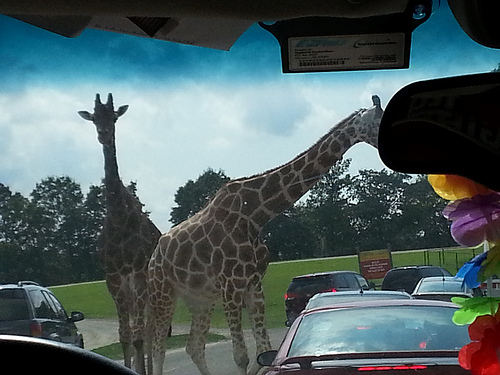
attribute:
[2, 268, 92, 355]
minivan — is gray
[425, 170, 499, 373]
stuff — colorful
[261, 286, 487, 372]
car — red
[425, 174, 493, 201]
flower — is black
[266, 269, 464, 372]
cars — are aligned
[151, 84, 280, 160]
sky — is cloudy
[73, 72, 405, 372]
giraffes — brown, white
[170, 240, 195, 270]
spot — brown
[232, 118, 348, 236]
neck — bent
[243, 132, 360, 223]
neck — long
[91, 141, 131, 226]
neck — long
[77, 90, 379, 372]
giraffes — are tall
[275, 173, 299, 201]
spot — brown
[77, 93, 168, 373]
giraffe — is spotted, tall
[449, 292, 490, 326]
green flower — is green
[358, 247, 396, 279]
sign — yellow and brown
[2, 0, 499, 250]
sky — blue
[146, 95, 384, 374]
giraffe — brown, beige, is spotted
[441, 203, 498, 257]
flower — red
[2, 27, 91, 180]
clouds — white 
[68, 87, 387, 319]
giraffe — looking right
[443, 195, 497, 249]
purple flower — is purple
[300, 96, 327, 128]
clouds — white